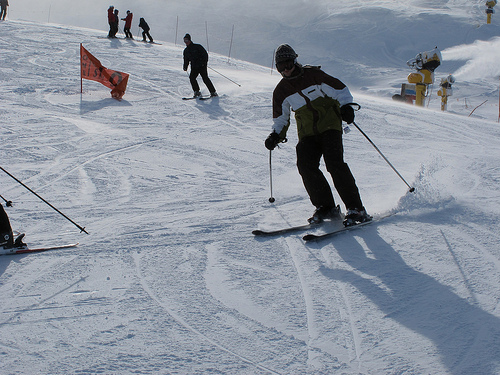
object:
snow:
[0, 0, 499, 375]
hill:
[0, 18, 273, 98]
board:
[302, 211, 397, 240]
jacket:
[271, 68, 353, 140]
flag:
[78, 42, 129, 101]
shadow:
[317, 228, 499, 375]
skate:
[0, 227, 81, 256]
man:
[264, 44, 374, 226]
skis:
[265, 121, 416, 205]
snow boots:
[307, 204, 373, 226]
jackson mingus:
[367, 5, 406, 18]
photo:
[0, 0, 499, 374]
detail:
[239, 14, 279, 34]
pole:
[224, 14, 236, 63]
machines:
[406, 46, 456, 112]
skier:
[181, 32, 219, 98]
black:
[181, 43, 217, 95]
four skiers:
[107, 5, 154, 44]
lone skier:
[0, 0, 8, 22]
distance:
[1, 0, 101, 26]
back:
[0, 167, 89, 235]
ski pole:
[0, 164, 90, 237]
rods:
[173, 10, 276, 75]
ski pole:
[268, 150, 276, 203]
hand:
[264, 131, 284, 150]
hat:
[274, 43, 298, 66]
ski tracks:
[90, 216, 250, 251]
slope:
[0, 19, 499, 374]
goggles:
[275, 58, 297, 73]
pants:
[295, 131, 363, 213]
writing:
[82, 56, 123, 87]